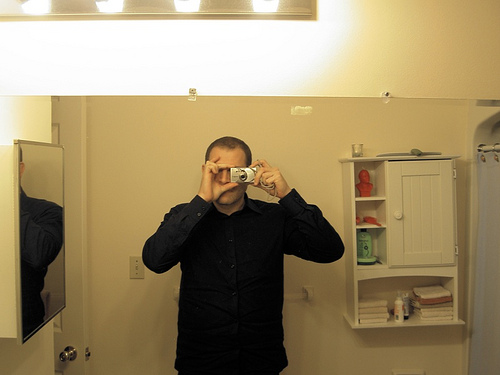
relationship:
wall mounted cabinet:
[89, 96, 499, 373] [346, 129, 466, 335]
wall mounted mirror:
[2, 97, 57, 374] [16, 141, 66, 342]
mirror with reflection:
[16, 141, 66, 342] [17, 147, 62, 334]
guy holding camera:
[141, 135, 341, 373] [228, 167, 262, 185]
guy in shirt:
[141, 136, 345, 375] [141, 189, 343, 369]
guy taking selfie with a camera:
[141, 136, 345, 375] [230, 166, 261, 183]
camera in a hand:
[230, 166, 258, 184] [246, 157, 291, 197]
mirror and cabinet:
[16, 142, 66, 337] [0, 140, 65, 343]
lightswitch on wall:
[129, 256, 143, 281] [89, 96, 499, 373]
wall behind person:
[89, 96, 499, 373] [138, 133, 348, 373]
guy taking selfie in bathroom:
[141, 136, 345, 375] [5, 3, 497, 360]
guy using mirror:
[141, 136, 345, 375] [0, 95, 498, 372]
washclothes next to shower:
[337, 135, 498, 334] [461, 102, 483, 351]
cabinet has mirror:
[0, 140, 65, 343] [16, 142, 66, 337]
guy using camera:
[141, 136, 345, 375] [215, 156, 282, 188]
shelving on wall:
[343, 151, 466, 330] [89, 96, 499, 373]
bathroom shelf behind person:
[339, 154, 469, 328] [160, 151, 345, 349]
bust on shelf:
[355, 171, 377, 200] [337, 149, 465, 330]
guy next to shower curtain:
[141, 136, 345, 375] [469, 137, 498, 372]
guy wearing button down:
[141, 136, 345, 375] [140, 189, 352, 367]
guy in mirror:
[141, 136, 345, 375] [16, 148, 78, 329]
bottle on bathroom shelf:
[391, 290, 408, 325] [339, 154, 469, 328]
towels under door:
[358, 298, 390, 324] [375, 159, 457, 268]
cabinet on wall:
[0, 138, 65, 348] [90, 154, 466, 371]